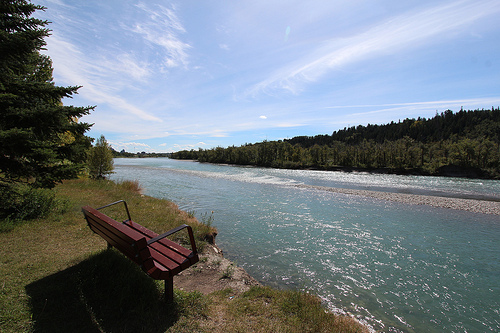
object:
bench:
[80, 199, 200, 304]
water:
[287, 222, 497, 278]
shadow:
[23, 247, 179, 333]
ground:
[3, 246, 90, 332]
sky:
[85, 1, 499, 105]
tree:
[0, 0, 98, 219]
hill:
[169, 106, 500, 179]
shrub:
[86, 134, 117, 181]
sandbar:
[290, 183, 500, 215]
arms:
[146, 224, 199, 255]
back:
[81, 205, 155, 274]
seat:
[116, 219, 199, 280]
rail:
[93, 199, 132, 220]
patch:
[162, 251, 257, 300]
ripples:
[320, 173, 371, 181]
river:
[282, 216, 498, 281]